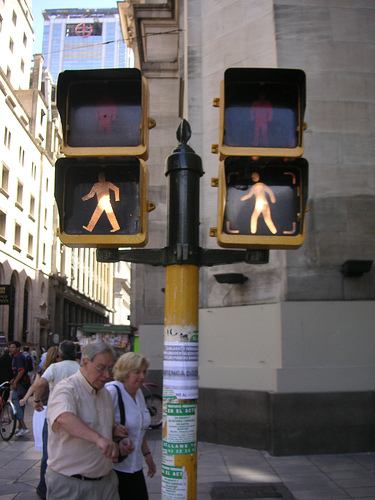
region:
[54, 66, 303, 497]
Traffic light on a city street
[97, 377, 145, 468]
Woman wearing white shirt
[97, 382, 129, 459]
Woman on city street wearing black purse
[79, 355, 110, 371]
Man on city street wearing eyeglasses.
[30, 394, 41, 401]
Watch located on a man's left arm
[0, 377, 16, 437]
Bike located on a city sidewalk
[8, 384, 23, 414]
Man wearing blue shorts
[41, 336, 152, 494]
Couple walking on the city sidewalk.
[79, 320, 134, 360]
Newstand on the city sidewalk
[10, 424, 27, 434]
Man wearing white tennis shoes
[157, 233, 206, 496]
metal post with black color clamp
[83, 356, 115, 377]
a person wearing eye glass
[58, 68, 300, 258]
traffic board with metal pole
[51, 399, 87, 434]
elbow of the person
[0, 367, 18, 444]
cycle parked near the building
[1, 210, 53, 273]
window with the building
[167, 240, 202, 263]
bolt in the metal pole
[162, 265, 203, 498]
yellow color metal pole with notices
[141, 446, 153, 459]
a woman wearing black color wrist watch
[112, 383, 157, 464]
a woman wearing white color shirt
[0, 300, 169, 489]
The people are walking in the city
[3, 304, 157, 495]
Some people are walking to somewhere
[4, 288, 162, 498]
The people are walking around slowly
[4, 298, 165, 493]
The people are going to their destination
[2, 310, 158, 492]
The people are minding their own business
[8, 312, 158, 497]
The people are on their lunch hour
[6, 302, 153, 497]
The people are going home after work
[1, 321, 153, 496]
The people are having a good time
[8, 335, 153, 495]
The people are out in the daytime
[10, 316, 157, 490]
The people are enjoying the day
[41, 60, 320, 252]
walk or do not walk signals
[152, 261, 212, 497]
yellow pole on walk signal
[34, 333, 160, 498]
man and woman walking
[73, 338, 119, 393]
head of man walking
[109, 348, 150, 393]
head of woman walking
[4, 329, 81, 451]
pedestrians walking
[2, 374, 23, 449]
bicycle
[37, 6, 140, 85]
top of skyscraper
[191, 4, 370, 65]
light colored blocks in building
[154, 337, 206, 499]
propaganda and notices stuck to sign post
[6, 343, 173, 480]
people walking on the street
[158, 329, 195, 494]
stickers on the pole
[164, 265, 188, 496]
a yellow pole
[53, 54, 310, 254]
yellow cross walk sign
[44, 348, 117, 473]
a an in a yellow shirt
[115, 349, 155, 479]
a woman in a white shirt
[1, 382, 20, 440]
a bicycle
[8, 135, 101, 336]
a white building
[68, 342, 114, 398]
a man wearing glasses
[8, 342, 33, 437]
a man in a blue shirt